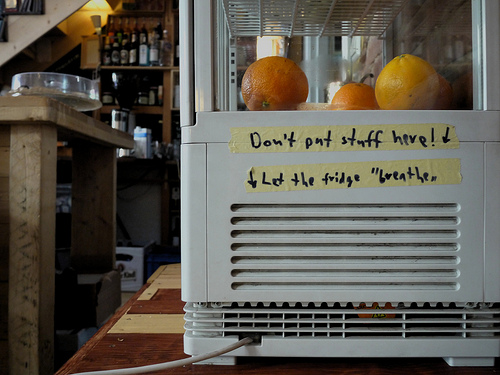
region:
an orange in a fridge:
[238, 54, 311, 109]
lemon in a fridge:
[373, 48, 445, 107]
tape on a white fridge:
[225, 123, 462, 153]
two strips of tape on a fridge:
[226, 121, 467, 191]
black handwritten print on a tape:
[241, 127, 454, 150]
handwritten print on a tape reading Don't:
[245, 130, 298, 148]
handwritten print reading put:
[300, 127, 335, 151]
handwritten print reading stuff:
[341, 127, 386, 149]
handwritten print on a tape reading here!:
[386, 128, 439, 149]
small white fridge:
[176, 0, 493, 367]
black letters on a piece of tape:
[230, 125, 457, 153]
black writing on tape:
[246, 164, 469, 194]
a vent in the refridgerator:
[234, 200, 459, 290]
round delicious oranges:
[240, 55, 439, 112]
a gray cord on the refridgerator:
[156, 352, 191, 371]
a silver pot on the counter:
[17, 71, 102, 102]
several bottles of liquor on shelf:
[104, 25, 166, 64]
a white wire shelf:
[229, 2, 393, 38]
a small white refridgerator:
[179, 2, 487, 374]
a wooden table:
[125, 272, 180, 359]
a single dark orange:
[236, 53, 310, 111]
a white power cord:
[60, 338, 258, 374]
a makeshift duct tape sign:
[232, 123, 464, 190]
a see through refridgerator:
[181, 0, 498, 363]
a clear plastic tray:
[10, 72, 104, 109]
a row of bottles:
[94, 16, 168, 68]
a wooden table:
[0, 95, 141, 373]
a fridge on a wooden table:
[60, 0, 497, 370]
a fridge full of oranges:
[185, 1, 498, 361]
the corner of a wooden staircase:
[1, 1, 106, 83]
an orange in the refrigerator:
[232, 37, 315, 120]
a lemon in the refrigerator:
[357, 39, 443, 114]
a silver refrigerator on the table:
[177, 2, 495, 362]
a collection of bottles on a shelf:
[99, 15, 166, 65]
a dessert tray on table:
[6, 62, 118, 113]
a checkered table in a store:
[93, 267, 185, 374]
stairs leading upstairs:
[0, 1, 90, 60]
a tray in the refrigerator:
[221, 2, 416, 44]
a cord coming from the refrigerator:
[61, 344, 252, 374]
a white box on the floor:
[114, 241, 150, 287]